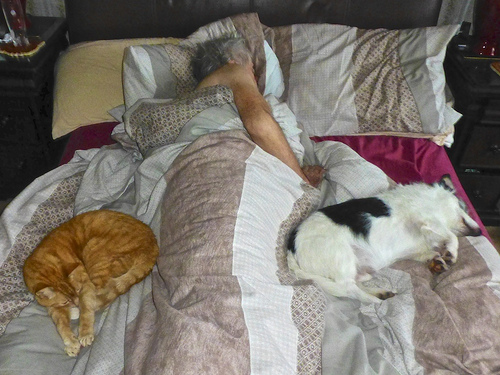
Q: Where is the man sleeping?
A: Middle.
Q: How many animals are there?
A: Two.